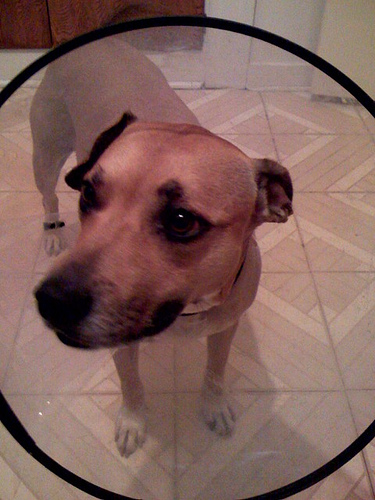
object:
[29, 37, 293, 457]
dog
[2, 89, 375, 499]
floor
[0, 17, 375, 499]
cone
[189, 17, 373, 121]
edge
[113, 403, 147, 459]
paw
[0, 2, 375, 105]
wall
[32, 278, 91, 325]
nose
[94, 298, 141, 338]
whiskers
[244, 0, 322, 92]
baseboard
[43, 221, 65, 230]
bracelet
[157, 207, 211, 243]
eye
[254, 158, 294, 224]
ear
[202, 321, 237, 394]
leg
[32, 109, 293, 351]
head